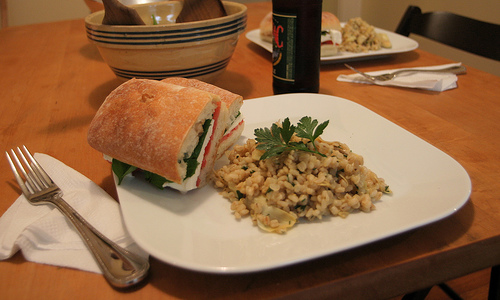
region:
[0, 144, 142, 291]
fork is on the napkin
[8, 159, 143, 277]
the napkin is white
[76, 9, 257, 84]
the bowl is woodden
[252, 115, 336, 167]
cilantro is on the food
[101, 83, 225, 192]
the bread is half cut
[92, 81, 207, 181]
the bread is brown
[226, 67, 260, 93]
shadow of the bowl is on the table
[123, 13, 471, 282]
two plates are on the table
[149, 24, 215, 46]
black stripes are on the bowl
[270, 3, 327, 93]
the bottle is black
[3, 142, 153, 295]
Fork on its back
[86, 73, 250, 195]
Pieces of sandwitches on a plate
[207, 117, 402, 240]
Dry scrambled eggs on a plate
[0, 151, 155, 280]
Paper towl on the table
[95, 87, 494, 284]
Wide plate with curved corners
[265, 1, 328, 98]
Datkk bottle with a label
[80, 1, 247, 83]
Brown wooden bowl with black colored rings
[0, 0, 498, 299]
Table with meal servings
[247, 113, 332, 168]
Vegetable leaf on the eggs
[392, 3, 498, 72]
Dark brown back of a chair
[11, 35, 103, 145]
Table is brown color.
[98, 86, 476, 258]
Plate is white color.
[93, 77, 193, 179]
Bread is brown color.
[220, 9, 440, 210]
Two plates of food is in the table.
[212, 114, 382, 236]
Rice is brown color.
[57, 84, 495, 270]
plate is square shape.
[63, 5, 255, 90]
Bowl is brown color.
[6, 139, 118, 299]
Fork is besides the table.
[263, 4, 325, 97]
Bottle is black color.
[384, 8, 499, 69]
Chair is brown color.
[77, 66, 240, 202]
Sandwich cut in half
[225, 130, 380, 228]
Brown rice side dish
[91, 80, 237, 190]
Caprese Sandwich cut in half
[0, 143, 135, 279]
Fork sitting on napkin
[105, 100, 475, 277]
Lunch sitting on white plate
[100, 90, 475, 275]
Lunch sitting on square plate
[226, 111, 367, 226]
Parsley garnish on side dish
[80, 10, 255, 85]
Ceramic bowl with stripes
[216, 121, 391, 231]
Brown rice and quinoa side dish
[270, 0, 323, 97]
beer bottle on table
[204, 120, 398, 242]
Rice on a plate.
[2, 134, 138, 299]
Metal fork on table.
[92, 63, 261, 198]
Sandwich on the plate.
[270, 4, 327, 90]
Beer bottle on table.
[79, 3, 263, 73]
Bowl in center of table.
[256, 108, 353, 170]
Parsley laying on rice.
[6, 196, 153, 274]
White napkin under fork.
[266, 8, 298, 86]
Label of beer bottle.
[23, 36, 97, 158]
A table made of wood.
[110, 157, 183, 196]
Spinach on a sandwich.